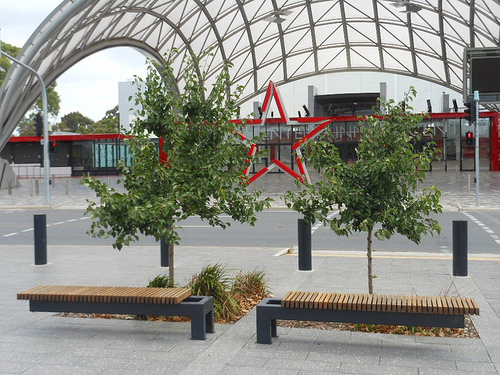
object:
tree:
[277, 84, 444, 293]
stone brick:
[0, 244, 500, 375]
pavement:
[0, 160, 500, 375]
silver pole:
[475, 102, 480, 195]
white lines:
[310, 208, 347, 235]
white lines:
[173, 224, 224, 228]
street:
[0, 159, 500, 375]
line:
[287, 250, 500, 262]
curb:
[285, 253, 500, 261]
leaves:
[97, 75, 453, 246]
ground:
[5, 156, 500, 373]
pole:
[453, 220, 470, 277]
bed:
[255, 291, 480, 345]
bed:
[16, 284, 214, 339]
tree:
[78, 43, 272, 288]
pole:
[0, 52, 52, 205]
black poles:
[34, 214, 48, 266]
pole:
[160, 234, 172, 266]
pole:
[297, 218, 313, 271]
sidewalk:
[0, 241, 500, 375]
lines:
[53, 221, 64, 224]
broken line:
[460, 210, 500, 245]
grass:
[132, 259, 277, 321]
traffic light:
[465, 131, 473, 147]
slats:
[283, 291, 480, 316]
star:
[219, 80, 336, 189]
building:
[0, 0, 500, 169]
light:
[468, 133, 472, 138]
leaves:
[285, 83, 442, 242]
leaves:
[345, 164, 394, 218]